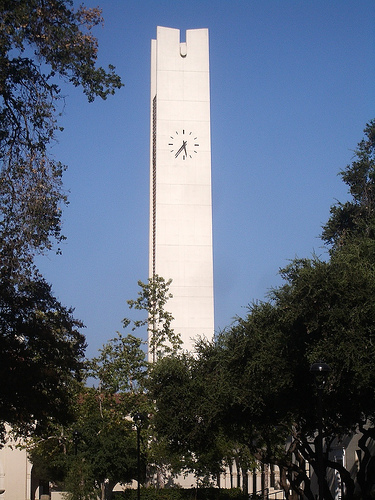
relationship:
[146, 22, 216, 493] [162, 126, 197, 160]
monument has clock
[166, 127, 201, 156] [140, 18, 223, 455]
clock on front of monument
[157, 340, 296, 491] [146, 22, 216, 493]
trees in front of monument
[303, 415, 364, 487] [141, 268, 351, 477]
building behind trees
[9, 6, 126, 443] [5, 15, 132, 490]
trees with leaves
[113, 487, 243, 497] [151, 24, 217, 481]
hedges in front of monument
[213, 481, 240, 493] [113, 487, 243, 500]
edge of hedges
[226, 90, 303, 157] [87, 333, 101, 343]
sky has clouds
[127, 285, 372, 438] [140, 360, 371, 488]
trees in row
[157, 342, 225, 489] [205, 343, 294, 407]
trees have leaves